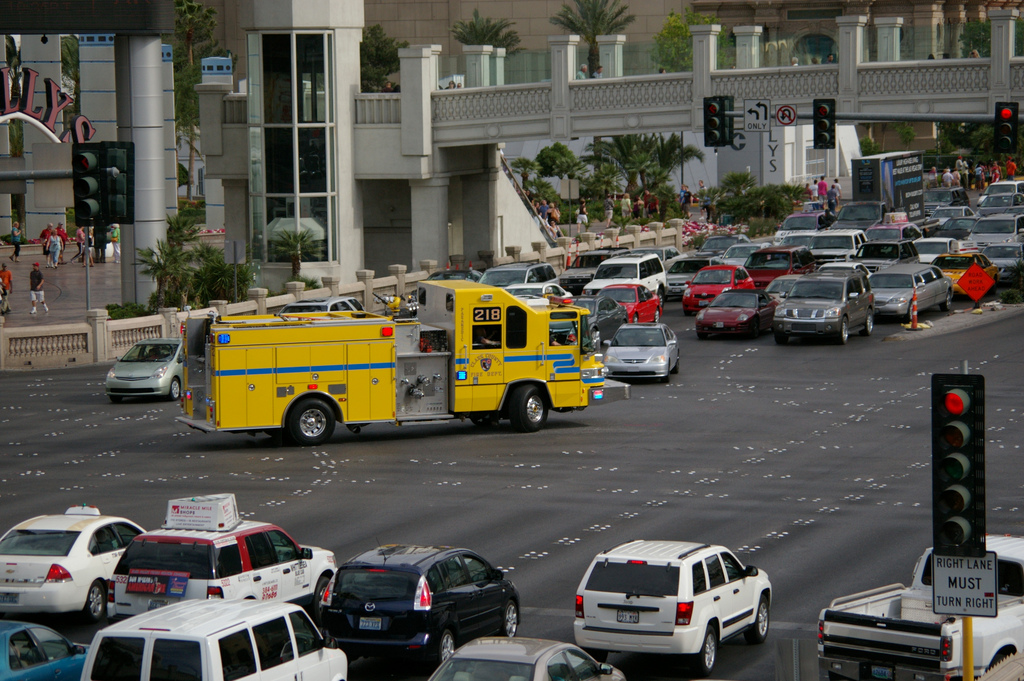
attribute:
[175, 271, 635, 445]
truck — Yellow 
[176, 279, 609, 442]
truck — Yellow 